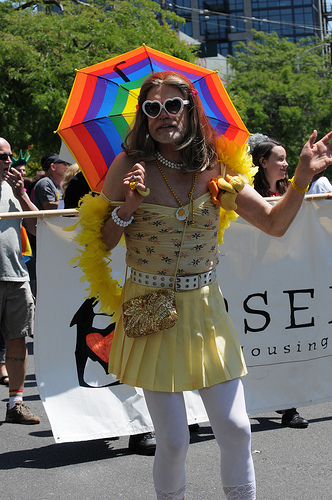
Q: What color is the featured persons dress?
A: Yellow.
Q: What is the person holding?
A: Umbrella.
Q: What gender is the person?
A: Male.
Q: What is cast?
A: Shadow.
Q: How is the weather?
A: Sunny.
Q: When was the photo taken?
A: Daytime.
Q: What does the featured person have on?
A: Sunglasses.